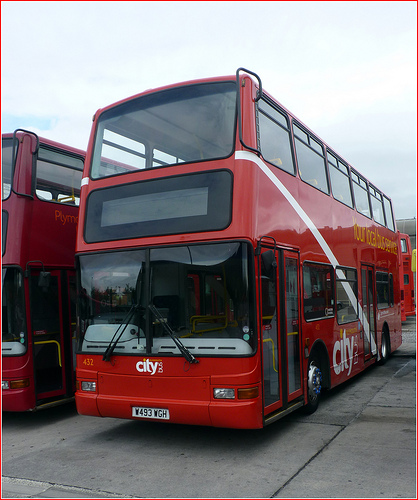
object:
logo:
[136, 358, 164, 376]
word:
[136, 358, 159, 375]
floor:
[1, 313, 416, 498]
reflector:
[261, 250, 278, 275]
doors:
[28, 264, 77, 406]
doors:
[362, 263, 378, 362]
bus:
[395, 230, 415, 321]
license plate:
[132, 407, 170, 421]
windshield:
[90, 79, 239, 180]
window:
[252, 95, 287, 169]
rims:
[307, 359, 323, 405]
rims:
[382, 337, 386, 357]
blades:
[102, 262, 143, 361]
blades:
[146, 268, 199, 363]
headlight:
[82, 382, 96, 392]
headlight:
[2, 380, 9, 389]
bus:
[74, 67, 401, 429]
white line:
[234, 150, 380, 361]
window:
[90, 81, 237, 180]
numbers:
[83, 358, 93, 365]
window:
[336, 268, 359, 324]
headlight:
[214, 388, 236, 399]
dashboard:
[81, 324, 253, 355]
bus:
[2, 131, 139, 413]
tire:
[302, 351, 322, 415]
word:
[333, 329, 355, 376]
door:
[252, 239, 284, 419]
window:
[291, 121, 329, 193]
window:
[327, 151, 355, 209]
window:
[351, 171, 372, 217]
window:
[369, 186, 385, 226]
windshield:
[76, 242, 254, 354]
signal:
[238, 386, 258, 398]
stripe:
[235, 150, 378, 355]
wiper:
[148, 268, 199, 364]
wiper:
[102, 262, 143, 361]